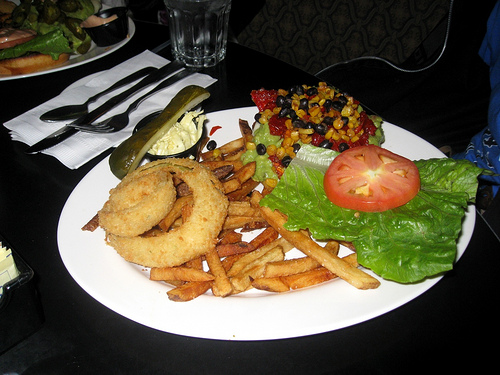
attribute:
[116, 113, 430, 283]
food — white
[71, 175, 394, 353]
plate — round 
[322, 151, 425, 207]
slice — unripe, tomatoe 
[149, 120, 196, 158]
cup — black 